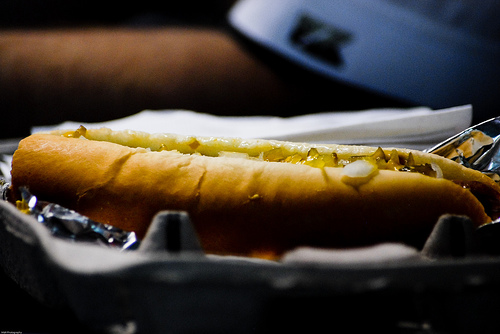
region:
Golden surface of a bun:
[54, 142, 124, 175]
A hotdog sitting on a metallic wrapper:
[7, 119, 498, 277]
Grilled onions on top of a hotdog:
[74, 124, 433, 184]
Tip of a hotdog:
[464, 168, 498, 220]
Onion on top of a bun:
[328, 155, 382, 192]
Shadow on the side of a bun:
[22, 172, 437, 245]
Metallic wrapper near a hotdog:
[40, 203, 132, 248]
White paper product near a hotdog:
[151, 98, 473, 150]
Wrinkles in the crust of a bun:
[92, 155, 207, 195]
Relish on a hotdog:
[306, 154, 328, 166]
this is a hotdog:
[10, 76, 490, 277]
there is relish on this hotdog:
[44, 115, 453, 186]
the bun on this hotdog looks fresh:
[23, 108, 478, 230]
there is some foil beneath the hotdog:
[11, 169, 158, 284]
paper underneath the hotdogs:
[8, 190, 498, 315]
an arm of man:
[5, 5, 487, 130]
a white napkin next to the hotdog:
[47, 90, 479, 150]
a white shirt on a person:
[227, 0, 491, 105]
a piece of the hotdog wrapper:
[420, 102, 498, 200]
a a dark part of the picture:
[7, 222, 495, 329]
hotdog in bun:
[3, 105, 498, 251]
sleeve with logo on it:
[231, 2, 484, 103]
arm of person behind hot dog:
[4, 25, 280, 114]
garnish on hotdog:
[60, 118, 450, 175]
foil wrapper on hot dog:
[28, 140, 498, 259]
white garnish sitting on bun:
[342, 160, 382, 185]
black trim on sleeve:
[213, 23, 423, 108]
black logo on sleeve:
[283, 7, 370, 73]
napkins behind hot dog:
[111, 96, 468, 144]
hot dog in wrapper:
[2, 113, 499, 310]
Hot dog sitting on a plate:
[11, 115, 480, 246]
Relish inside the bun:
[72, 117, 338, 173]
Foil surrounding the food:
[424, 122, 497, 155]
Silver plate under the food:
[40, 223, 135, 283]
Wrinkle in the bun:
[72, 157, 232, 209]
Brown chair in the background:
[7, 12, 198, 93]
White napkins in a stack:
[142, 107, 401, 136]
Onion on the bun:
[325, 149, 382, 179]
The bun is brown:
[12, 115, 484, 224]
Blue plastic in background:
[222, 9, 487, 90]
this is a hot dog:
[37, 120, 377, 210]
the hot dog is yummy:
[50, 127, 381, 202]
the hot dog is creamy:
[294, 148, 327, 165]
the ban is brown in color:
[264, 171, 324, 238]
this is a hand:
[102, 35, 206, 102]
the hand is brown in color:
[121, 30, 213, 91]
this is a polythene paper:
[56, 208, 99, 244]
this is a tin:
[363, 25, 427, 80]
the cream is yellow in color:
[303, 148, 333, 163]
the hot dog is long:
[25, 144, 473, 194]